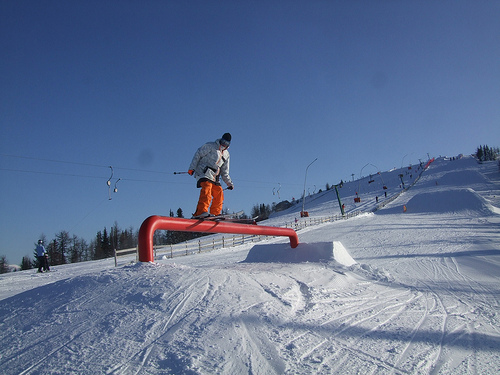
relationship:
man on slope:
[187, 132, 235, 225] [0, 156, 499, 372]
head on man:
[202, 130, 236, 143] [187, 132, 235, 225]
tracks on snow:
[0, 200, 499, 372] [1, 272, 498, 373]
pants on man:
[200, 182, 225, 215] [187, 132, 235, 225]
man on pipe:
[182, 113, 239, 225] [138, 217, 298, 263]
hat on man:
[218, 132, 233, 145] [158, 93, 288, 265]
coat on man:
[200, 120, 221, 169] [187, 132, 235, 225]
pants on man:
[193, 180, 225, 215] [188, 122, 237, 222]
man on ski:
[187, 132, 235, 225] [214, 212, 233, 221]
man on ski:
[187, 132, 235, 225] [189, 212, 218, 220]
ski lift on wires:
[99, 156, 129, 205] [0, 151, 330, 197]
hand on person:
[184, 168, 199, 177] [189, 129, 239, 216]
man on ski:
[187, 132, 235, 225] [194, 209, 245, 221]